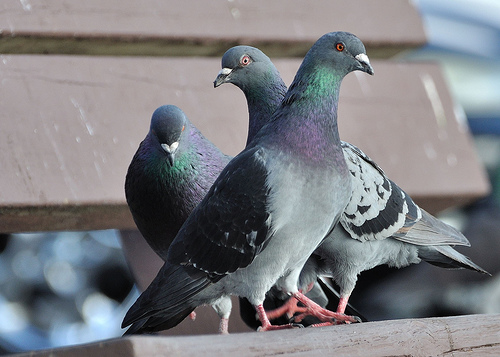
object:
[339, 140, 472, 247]
wing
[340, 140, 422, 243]
feathers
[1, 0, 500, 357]
brown bench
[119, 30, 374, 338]
pigeon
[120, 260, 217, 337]
tailfethers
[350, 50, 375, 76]
beak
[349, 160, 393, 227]
markings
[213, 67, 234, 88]
beak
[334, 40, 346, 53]
eye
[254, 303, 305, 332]
feet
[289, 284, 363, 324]
feet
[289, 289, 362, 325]
feet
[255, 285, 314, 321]
feet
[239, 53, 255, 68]
pigeon's eye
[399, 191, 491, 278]
tail feathers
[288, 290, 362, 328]
claw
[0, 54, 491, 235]
boards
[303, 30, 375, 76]
head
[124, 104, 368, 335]
pigeon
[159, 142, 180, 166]
pigeon's beak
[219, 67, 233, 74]
white beak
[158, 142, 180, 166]
beak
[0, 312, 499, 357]
bench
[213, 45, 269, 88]
heads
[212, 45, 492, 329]
pigeon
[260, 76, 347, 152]
neck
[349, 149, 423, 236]
stripes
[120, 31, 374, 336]
bird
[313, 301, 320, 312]
part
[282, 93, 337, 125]
multicolored feathers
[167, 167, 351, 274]
feathers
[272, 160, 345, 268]
abdomens